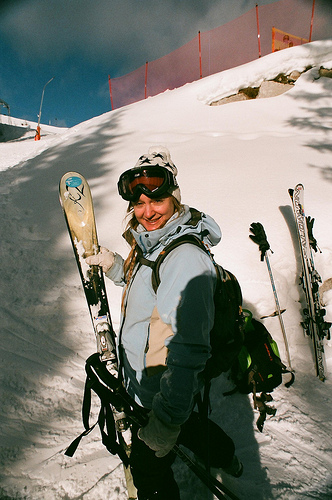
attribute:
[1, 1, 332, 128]
sky — blue, cloudy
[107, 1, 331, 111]
fence — red, orange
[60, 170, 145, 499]
skis — here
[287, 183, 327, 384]
pole — black, here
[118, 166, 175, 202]
goggles — large, black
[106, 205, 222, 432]
top — blue, tan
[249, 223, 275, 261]
gloves — black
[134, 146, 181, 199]
hat — white, black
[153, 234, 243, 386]
backpack — green, grey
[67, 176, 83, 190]
circle — blue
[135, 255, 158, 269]
string — black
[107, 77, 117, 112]
pole — red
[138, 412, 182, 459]
glove — white